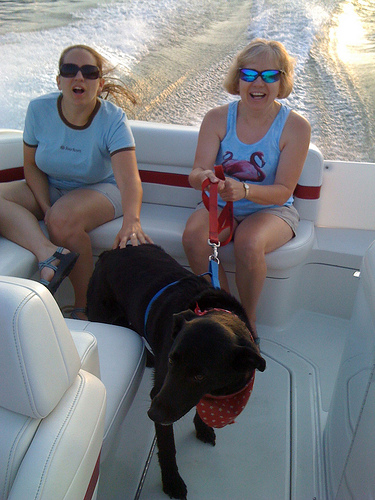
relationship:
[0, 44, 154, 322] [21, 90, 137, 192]
lady wearing shirt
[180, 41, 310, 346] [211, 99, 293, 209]
lady wearing shirt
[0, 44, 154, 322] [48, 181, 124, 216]
lady wearing shorts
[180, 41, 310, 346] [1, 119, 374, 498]
lady sitting on boat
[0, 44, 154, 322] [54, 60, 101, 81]
lady wearing sun shades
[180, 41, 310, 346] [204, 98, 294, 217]
lady wearing tank top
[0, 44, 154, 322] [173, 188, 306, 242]
lady wearing shorts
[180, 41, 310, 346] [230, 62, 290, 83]
lady wearing shades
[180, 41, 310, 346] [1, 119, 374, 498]
lady wearing boat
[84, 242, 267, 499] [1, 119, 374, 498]
dog in boat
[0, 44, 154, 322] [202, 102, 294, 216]
lady in shirt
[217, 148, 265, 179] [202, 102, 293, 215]
flamingos in shirt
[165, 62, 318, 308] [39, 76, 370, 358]
lady in boat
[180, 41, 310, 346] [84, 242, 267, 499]
lady with dog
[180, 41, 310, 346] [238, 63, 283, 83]
lady with sunglasses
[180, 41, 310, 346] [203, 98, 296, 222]
lady with shirt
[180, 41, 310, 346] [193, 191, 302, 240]
lady with shorts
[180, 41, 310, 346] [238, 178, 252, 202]
lady with watch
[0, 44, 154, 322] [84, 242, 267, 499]
lady pets dog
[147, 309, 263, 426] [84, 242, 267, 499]
head of dog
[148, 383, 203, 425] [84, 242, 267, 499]
mouth of a dog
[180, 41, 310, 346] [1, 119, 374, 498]
lady on a boat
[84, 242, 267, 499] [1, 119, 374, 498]
dog on a boat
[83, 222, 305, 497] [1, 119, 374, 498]
dog on boat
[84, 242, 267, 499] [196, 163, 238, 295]
dog has a leach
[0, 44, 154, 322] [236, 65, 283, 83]
lady wearing sunglasses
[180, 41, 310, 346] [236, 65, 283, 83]
lady wearing sunglasses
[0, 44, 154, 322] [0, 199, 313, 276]
lady sitting on boat seat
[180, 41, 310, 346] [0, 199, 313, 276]
lady sitting on boat seat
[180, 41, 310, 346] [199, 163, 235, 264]
lady holding leash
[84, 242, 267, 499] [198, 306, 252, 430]
dog wearing bandana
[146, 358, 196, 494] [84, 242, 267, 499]
leg of dog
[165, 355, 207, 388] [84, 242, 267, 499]
dog's eye of dog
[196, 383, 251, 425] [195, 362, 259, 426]
dots on bandana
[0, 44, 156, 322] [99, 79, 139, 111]
lady has ponytail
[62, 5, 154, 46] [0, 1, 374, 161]
bubbles on ocean